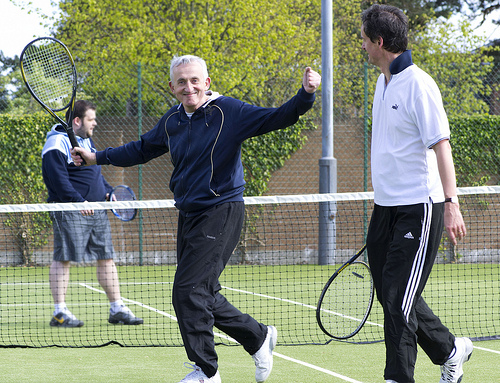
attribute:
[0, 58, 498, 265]
fence — green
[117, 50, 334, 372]
man — happy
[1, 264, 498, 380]
tennis court — green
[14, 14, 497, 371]
court — tennis court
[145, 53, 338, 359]
man — walking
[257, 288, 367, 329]
lines — white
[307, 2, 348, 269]
post — metal, light post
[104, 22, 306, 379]
man — smiling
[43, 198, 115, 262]
shorts — grey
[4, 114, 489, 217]
ivy — leafy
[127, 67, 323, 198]
shirt — blue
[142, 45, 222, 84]
hair — grey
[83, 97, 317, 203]
jacket — blue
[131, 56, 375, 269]
post — green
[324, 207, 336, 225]
bolt — rusty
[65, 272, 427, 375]
lines — white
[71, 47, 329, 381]
man — happy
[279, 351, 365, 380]
line — white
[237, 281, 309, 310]
line — white